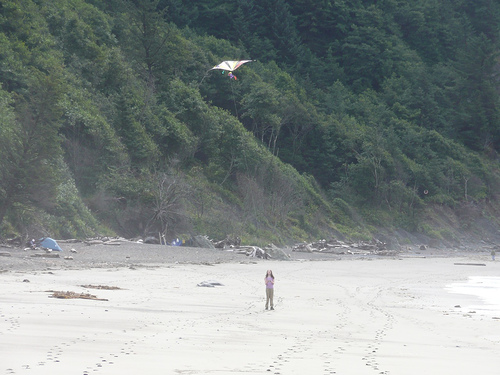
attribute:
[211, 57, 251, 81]
kite — white 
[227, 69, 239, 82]
tail — small 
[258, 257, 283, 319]
girl — looking up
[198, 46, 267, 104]
kite — flying, colorful